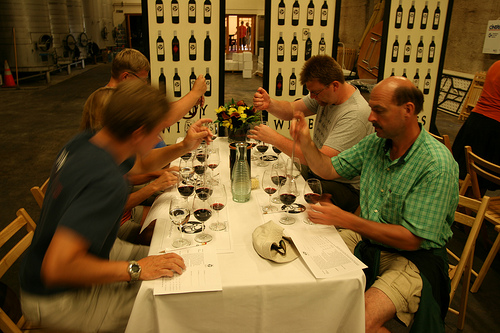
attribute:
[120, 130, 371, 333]
table — long, rectangular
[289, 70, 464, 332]
person — seated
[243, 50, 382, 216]
person — seated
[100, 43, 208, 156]
person — seated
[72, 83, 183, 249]
person — seated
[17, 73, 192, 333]
person — seated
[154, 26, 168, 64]
picture — bottle, wine bottle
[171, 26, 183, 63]
picture — bottle, wine bottle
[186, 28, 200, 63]
picture — bottle, wine bottle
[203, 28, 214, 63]
picture — bottle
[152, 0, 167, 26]
picture — bottle, wine bottle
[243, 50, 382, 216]
man — white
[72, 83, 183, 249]
woman — writing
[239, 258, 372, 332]
table cloth — white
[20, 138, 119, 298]
top — blue, grey, black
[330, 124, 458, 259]
shirt — green, checkered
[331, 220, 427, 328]
shorts — brown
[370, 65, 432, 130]
head — bald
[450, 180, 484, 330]
chair — wooden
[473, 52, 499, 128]
top — red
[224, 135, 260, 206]
vase — empty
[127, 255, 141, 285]
watch — silver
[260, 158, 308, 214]
glasses — half full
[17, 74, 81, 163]
floor — grey